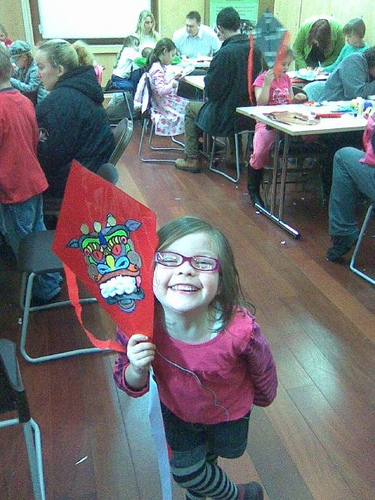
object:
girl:
[114, 214, 280, 500]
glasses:
[154, 250, 223, 276]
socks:
[168, 456, 240, 499]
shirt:
[111, 293, 278, 423]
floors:
[2, 147, 375, 496]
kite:
[52, 159, 158, 354]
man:
[173, 5, 270, 173]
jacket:
[194, 33, 270, 137]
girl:
[247, 45, 307, 209]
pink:
[257, 76, 289, 103]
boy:
[0, 41, 65, 300]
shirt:
[0, 89, 49, 205]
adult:
[291, 18, 346, 71]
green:
[304, 65, 322, 75]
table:
[233, 99, 373, 285]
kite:
[247, 6, 291, 105]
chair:
[209, 95, 256, 184]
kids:
[110, 18, 370, 210]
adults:
[50, 158, 160, 357]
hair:
[49, 39, 94, 73]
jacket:
[290, 19, 345, 70]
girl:
[9, 39, 50, 104]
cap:
[9, 39, 32, 62]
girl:
[146, 38, 192, 136]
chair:
[138, 72, 186, 164]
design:
[64, 214, 142, 315]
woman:
[36, 38, 116, 200]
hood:
[52, 64, 105, 104]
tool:
[313, 113, 343, 119]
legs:
[270, 129, 290, 221]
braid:
[113, 45, 126, 69]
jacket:
[35, 64, 117, 198]